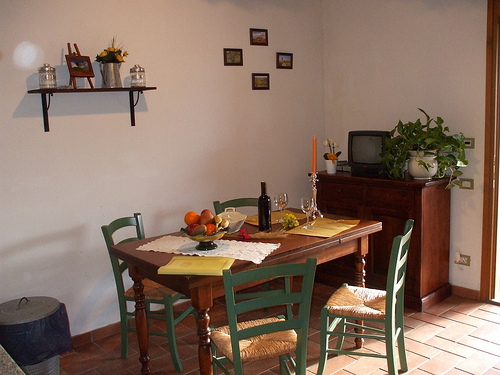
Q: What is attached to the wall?
A: Shelf.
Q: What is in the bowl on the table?
A: Fruit.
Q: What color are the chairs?
A: Green.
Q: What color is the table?
A: Brown.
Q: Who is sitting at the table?
A: Nobody.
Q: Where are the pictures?
A: Wall.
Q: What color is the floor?
A: Brown.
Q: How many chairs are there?
A: Four.